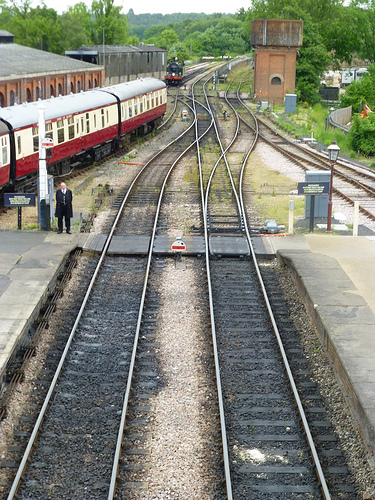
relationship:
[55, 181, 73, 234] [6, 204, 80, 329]
man standing on pavement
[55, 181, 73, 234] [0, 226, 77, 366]
man standing on pavement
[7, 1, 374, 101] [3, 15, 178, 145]
trees behind train station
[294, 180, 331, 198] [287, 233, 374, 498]
sign at end of platform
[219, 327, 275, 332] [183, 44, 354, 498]
tie on track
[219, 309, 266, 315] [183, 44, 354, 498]
tie on track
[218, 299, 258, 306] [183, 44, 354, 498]
tie on track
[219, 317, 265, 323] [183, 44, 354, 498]
tie on track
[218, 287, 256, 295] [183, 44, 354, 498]
tie on track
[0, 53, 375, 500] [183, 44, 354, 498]
rail on track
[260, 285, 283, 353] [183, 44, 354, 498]
rail on track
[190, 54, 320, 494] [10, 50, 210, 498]
track crossing track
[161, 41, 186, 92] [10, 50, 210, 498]
train car sitting on track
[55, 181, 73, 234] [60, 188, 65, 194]
man wearing white shirt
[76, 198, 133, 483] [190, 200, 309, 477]
train track next to train track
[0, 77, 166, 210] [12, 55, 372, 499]
train on tracks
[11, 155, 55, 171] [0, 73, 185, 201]
trim on train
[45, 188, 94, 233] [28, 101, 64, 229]
man standing next to pole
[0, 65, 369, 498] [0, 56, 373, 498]
gravel on train tracks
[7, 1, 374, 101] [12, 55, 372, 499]
trees near tracks